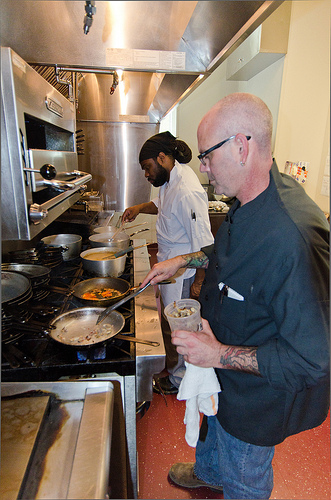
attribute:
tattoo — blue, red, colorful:
[178, 252, 210, 271]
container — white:
[163, 300, 204, 341]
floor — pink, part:
[138, 240, 330, 500]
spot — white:
[171, 444, 180, 450]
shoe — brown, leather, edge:
[164, 460, 215, 490]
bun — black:
[173, 140, 192, 164]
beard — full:
[147, 165, 174, 188]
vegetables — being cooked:
[81, 285, 122, 299]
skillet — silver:
[68, 279, 150, 304]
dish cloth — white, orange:
[290, 163, 311, 184]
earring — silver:
[236, 158, 246, 170]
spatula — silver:
[89, 280, 156, 329]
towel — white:
[176, 341, 222, 447]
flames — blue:
[74, 340, 108, 361]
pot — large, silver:
[78, 244, 147, 274]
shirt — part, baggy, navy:
[195, 159, 329, 450]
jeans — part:
[188, 419, 281, 500]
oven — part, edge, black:
[2, 243, 163, 500]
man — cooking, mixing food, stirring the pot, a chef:
[111, 89, 329, 499]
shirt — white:
[149, 162, 210, 275]